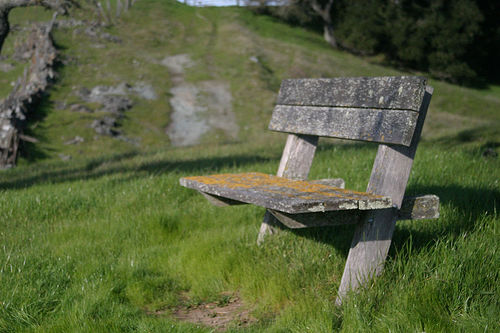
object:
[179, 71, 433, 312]
bench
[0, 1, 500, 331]
field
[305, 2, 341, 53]
tree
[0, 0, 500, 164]
back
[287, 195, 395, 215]
paint scrapings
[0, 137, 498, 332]
grass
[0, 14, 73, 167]
wall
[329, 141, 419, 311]
bar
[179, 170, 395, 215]
seat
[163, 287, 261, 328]
spot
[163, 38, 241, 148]
path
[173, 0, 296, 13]
sky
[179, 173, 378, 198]
moss